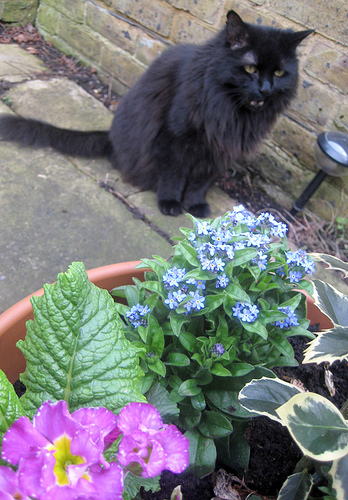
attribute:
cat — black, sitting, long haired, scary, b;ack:
[2, 8, 316, 222]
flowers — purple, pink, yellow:
[1, 396, 190, 498]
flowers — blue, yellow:
[232, 300, 261, 323]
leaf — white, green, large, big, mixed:
[274, 390, 347, 460]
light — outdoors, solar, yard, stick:
[287, 130, 347, 223]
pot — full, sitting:
[1, 257, 347, 495]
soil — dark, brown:
[9, 323, 346, 495]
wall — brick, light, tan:
[3, 2, 347, 237]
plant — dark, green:
[154, 315, 275, 478]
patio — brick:
[1, 39, 347, 326]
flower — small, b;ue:
[213, 342, 224, 353]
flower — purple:
[116, 402, 161, 438]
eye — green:
[243, 66, 257, 76]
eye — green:
[273, 70, 283, 78]